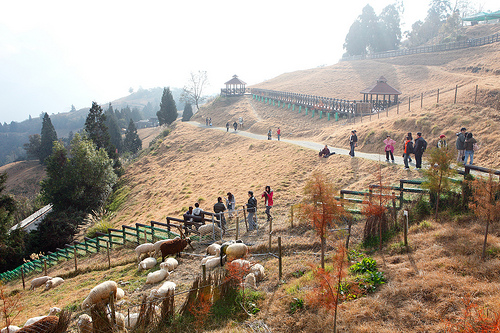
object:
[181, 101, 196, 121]
tree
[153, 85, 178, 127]
tree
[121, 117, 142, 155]
tree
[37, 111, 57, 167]
tree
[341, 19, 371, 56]
tree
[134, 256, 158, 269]
sheep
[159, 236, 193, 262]
sheep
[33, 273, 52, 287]
sheep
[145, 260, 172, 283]
sheep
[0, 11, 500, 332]
hillside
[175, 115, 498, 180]
sidewalk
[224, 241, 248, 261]
animals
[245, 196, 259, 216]
jacket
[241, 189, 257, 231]
man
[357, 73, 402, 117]
gazebos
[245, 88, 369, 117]
walkway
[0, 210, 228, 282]
fence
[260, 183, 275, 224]
girl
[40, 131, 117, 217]
trees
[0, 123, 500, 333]
grass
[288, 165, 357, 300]
trees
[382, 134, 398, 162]
people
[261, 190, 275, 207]
shirt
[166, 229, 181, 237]
stairs